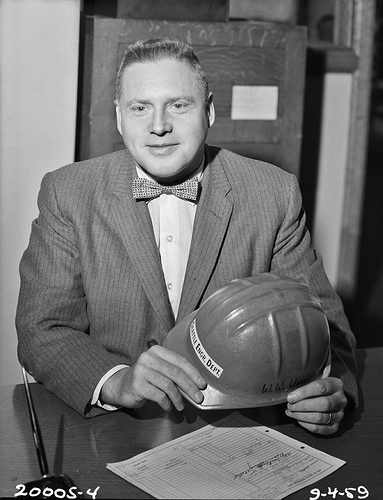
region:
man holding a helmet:
[180, 276, 322, 404]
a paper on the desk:
[142, 442, 324, 498]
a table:
[104, 419, 165, 447]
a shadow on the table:
[50, 417, 87, 464]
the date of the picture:
[307, 484, 369, 498]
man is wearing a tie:
[128, 176, 204, 203]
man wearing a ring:
[322, 411, 335, 426]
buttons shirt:
[163, 225, 183, 291]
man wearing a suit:
[46, 187, 119, 356]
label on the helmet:
[187, 325, 231, 376]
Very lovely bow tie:
[125, 170, 213, 208]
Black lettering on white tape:
[182, 317, 229, 381]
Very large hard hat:
[142, 265, 337, 423]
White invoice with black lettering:
[94, 416, 336, 498]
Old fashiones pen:
[10, 362, 76, 497]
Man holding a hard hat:
[41, 34, 353, 371]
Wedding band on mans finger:
[263, 371, 340, 435]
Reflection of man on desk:
[61, 422, 172, 498]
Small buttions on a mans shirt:
[154, 221, 182, 300]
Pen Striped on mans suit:
[55, 211, 138, 345]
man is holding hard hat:
[158, 263, 322, 406]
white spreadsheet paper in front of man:
[77, 418, 337, 498]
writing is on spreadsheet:
[114, 426, 342, 498]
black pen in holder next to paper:
[12, 363, 73, 483]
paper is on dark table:
[94, 410, 329, 489]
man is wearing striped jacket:
[34, 166, 316, 391]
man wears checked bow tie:
[132, 172, 202, 203]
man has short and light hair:
[108, 21, 234, 98]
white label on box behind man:
[227, 84, 284, 123]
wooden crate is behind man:
[128, 13, 305, 170]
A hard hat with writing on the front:
[160, 271, 338, 410]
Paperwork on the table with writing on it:
[85, 413, 350, 498]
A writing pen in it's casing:
[16, 358, 51, 479]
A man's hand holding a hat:
[114, 343, 209, 415]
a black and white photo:
[17, 20, 381, 479]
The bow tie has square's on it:
[128, 175, 201, 200]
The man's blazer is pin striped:
[13, 150, 363, 419]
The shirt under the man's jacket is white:
[138, 194, 198, 314]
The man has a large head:
[104, 34, 218, 180]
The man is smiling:
[139, 136, 183, 158]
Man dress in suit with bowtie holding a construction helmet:
[6, 5, 364, 436]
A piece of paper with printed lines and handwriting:
[111, 413, 344, 497]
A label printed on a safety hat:
[189, 317, 219, 379]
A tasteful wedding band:
[325, 411, 334, 425]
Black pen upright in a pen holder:
[18, 364, 66, 498]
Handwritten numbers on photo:
[10, 480, 99, 498]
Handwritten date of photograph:
[305, 482, 375, 497]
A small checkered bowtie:
[130, 175, 199, 202]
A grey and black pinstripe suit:
[15, 159, 360, 430]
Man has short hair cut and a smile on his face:
[107, 35, 215, 180]